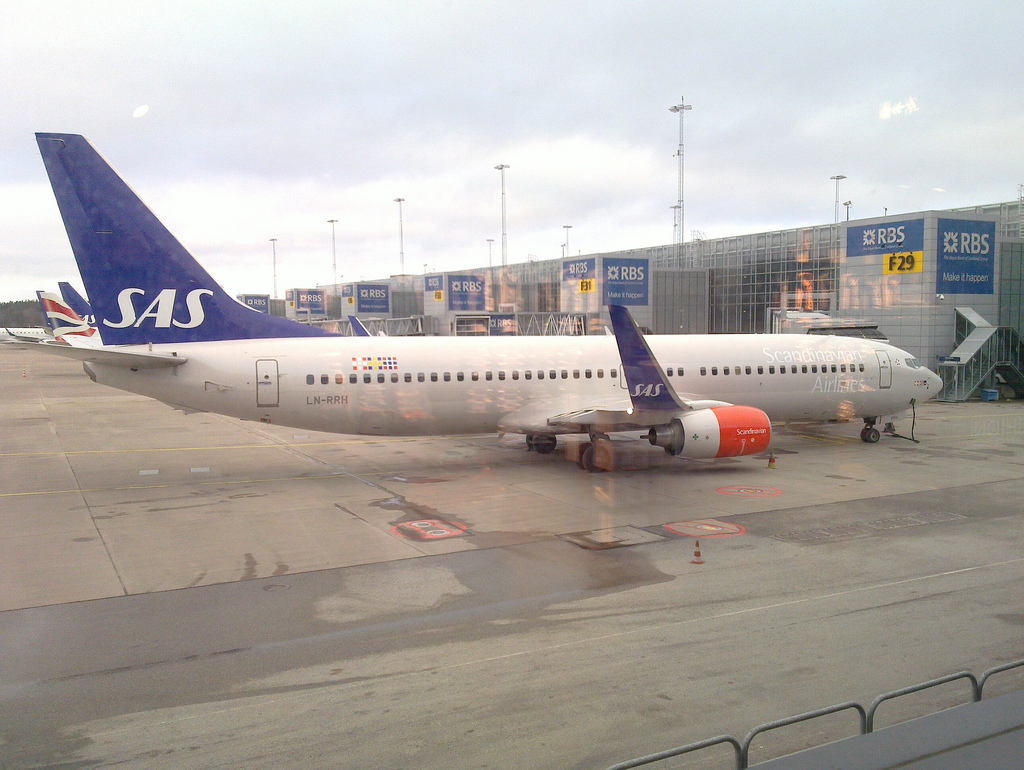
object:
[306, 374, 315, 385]
window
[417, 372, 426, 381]
window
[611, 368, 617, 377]
window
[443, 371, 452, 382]
window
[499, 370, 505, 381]
window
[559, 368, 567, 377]
window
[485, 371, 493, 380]
window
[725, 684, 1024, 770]
walkway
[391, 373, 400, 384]
window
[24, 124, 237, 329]
tail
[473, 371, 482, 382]
window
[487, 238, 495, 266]
poles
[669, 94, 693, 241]
poles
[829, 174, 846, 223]
poles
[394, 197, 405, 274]
poles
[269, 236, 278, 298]
poles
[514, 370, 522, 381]
window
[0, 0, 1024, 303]
sky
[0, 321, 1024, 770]
tarmac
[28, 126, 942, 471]
plane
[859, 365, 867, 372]
window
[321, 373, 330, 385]
window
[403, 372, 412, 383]
window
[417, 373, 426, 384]
window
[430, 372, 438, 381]
window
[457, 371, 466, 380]
window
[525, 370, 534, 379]
window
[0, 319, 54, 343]
plane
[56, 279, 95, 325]
plane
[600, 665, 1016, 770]
rail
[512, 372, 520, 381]
window